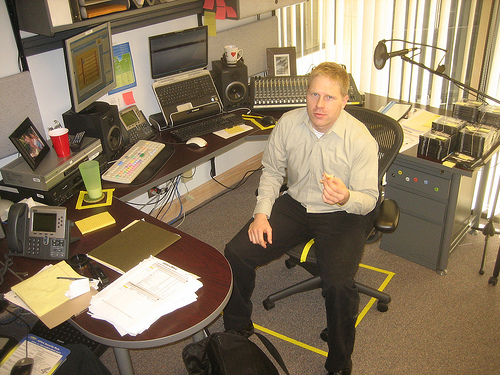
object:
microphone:
[373, 37, 419, 69]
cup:
[49, 128, 72, 160]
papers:
[88, 255, 204, 338]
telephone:
[5, 204, 81, 262]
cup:
[77, 161, 104, 200]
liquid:
[87, 187, 103, 200]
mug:
[223, 46, 244, 68]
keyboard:
[101, 138, 166, 183]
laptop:
[147, 26, 225, 128]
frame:
[9, 117, 52, 172]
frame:
[267, 47, 297, 79]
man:
[225, 58, 381, 369]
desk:
[2, 90, 498, 374]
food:
[321, 173, 344, 185]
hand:
[321, 173, 354, 207]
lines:
[252, 262, 395, 360]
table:
[2, 179, 235, 374]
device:
[0, 131, 104, 193]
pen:
[54, 276, 93, 280]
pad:
[12, 260, 99, 329]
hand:
[249, 215, 276, 252]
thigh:
[229, 195, 314, 261]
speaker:
[211, 60, 251, 111]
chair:
[253, 104, 402, 341]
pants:
[224, 192, 378, 373]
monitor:
[62, 21, 118, 114]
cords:
[126, 157, 264, 233]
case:
[182, 323, 292, 374]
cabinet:
[379, 146, 485, 276]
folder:
[84, 216, 180, 275]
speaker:
[62, 100, 126, 161]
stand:
[149, 113, 232, 130]